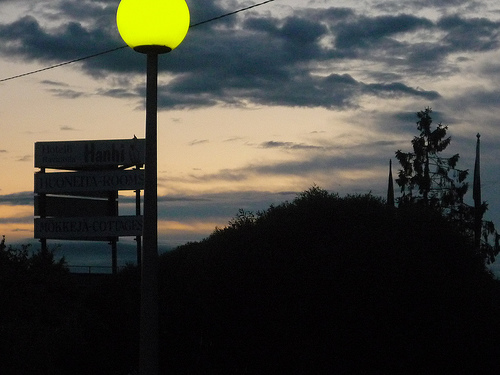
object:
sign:
[34, 138, 144, 169]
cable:
[0, 0, 274, 82]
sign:
[30, 215, 144, 238]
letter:
[83, 174, 97, 189]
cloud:
[59, 125, 74, 137]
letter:
[102, 176, 114, 189]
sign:
[34, 195, 119, 223]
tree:
[391, 105, 499, 267]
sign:
[32, 171, 147, 193]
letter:
[37, 177, 49, 189]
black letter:
[110, 141, 120, 164]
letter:
[117, 145, 126, 166]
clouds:
[182, 138, 210, 148]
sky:
[0, 0, 499, 275]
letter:
[83, 143, 96, 165]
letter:
[92, 148, 102, 166]